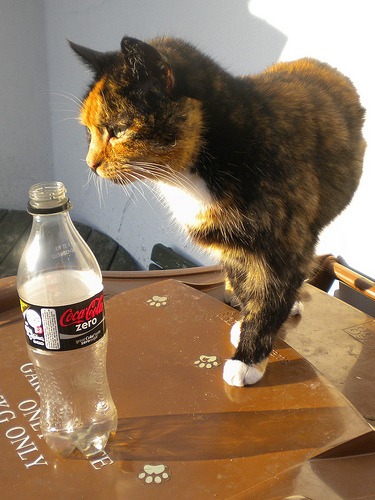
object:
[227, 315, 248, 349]
paw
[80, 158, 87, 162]
white whiskers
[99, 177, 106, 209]
white whiskers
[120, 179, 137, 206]
white whiskers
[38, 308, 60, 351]
label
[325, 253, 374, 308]
handle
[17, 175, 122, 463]
bottle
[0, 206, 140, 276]
wood table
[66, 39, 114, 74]
ear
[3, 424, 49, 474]
words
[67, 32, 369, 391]
cat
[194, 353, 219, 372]
pawprints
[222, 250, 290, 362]
leg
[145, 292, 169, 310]
paw print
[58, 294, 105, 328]
identification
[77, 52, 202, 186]
face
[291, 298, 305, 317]
white paw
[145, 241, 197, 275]
wooden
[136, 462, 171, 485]
paw print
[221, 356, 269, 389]
paw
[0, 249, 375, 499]
furniture piece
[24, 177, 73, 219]
top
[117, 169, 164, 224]
whiskers